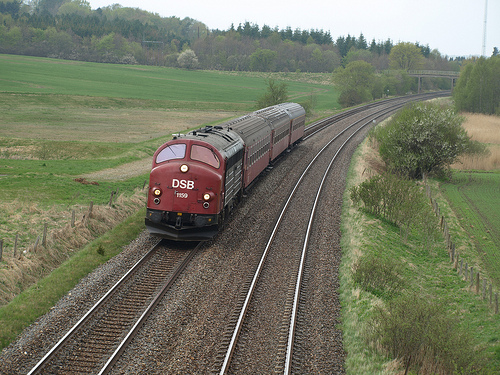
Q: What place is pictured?
A: It is a field.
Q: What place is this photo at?
A: It is at the field.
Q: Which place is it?
A: It is a field.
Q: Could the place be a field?
A: Yes, it is a field.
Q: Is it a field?
A: Yes, it is a field.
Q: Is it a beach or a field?
A: It is a field.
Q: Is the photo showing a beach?
A: No, the picture is showing a field.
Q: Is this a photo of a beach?
A: No, the picture is showing a field.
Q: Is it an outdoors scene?
A: Yes, it is outdoors.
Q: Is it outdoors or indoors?
A: It is outdoors.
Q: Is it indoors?
A: No, it is outdoors.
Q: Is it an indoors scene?
A: No, it is outdoors.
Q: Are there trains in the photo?
A: Yes, there is a train.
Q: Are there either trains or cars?
A: Yes, there is a train.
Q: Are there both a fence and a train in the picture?
A: Yes, there are both a train and a fence.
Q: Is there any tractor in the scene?
A: No, there are no tractors.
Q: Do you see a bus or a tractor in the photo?
A: No, there are no tractors or buses.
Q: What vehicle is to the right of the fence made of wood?
A: The vehicle is a train.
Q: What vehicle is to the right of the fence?
A: The vehicle is a train.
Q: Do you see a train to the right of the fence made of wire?
A: Yes, there is a train to the right of the fence.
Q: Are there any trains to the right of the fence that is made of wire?
A: Yes, there is a train to the right of the fence.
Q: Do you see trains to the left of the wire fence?
A: No, the train is to the right of the fence.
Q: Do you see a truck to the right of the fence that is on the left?
A: No, there is a train to the right of the fence.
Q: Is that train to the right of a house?
A: No, the train is to the right of a fence.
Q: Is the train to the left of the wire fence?
A: No, the train is to the right of the fence.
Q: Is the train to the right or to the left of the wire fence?
A: The train is to the right of the fence.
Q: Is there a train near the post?
A: Yes, there is a train near the post.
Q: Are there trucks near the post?
A: No, there is a train near the post.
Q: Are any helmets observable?
A: No, there are no helmets.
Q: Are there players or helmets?
A: No, there are no helmets or players.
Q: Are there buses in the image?
A: No, there are no buses.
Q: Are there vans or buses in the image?
A: No, there are no buses or vans.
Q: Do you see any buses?
A: No, there are no buses.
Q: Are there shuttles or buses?
A: No, there are no buses or shuttles.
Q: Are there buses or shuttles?
A: No, there are no buses or shuttles.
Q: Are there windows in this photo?
A: Yes, there is a window.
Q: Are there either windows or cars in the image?
A: Yes, there is a window.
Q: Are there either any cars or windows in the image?
A: Yes, there is a window.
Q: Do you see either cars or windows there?
A: Yes, there is a window.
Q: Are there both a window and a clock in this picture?
A: No, there is a window but no clocks.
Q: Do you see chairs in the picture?
A: No, there are no chairs.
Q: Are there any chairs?
A: No, there are no chairs.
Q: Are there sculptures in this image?
A: No, there are no sculptures.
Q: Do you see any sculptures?
A: No, there are no sculptures.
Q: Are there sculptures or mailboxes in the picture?
A: No, there are no sculptures or mailboxes.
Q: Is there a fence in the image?
A: Yes, there is a fence.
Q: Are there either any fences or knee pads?
A: Yes, there is a fence.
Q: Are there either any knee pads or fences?
A: Yes, there is a fence.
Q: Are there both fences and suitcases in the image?
A: No, there is a fence but no suitcases.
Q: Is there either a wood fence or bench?
A: Yes, there is a wood fence.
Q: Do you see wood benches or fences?
A: Yes, there is a wood fence.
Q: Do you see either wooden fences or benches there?
A: Yes, there is a wood fence.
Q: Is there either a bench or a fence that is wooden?
A: Yes, the fence is wooden.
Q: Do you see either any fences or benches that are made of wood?
A: Yes, the fence is made of wood.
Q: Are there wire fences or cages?
A: Yes, there is a wire fence.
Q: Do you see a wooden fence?
A: Yes, there is a wood fence.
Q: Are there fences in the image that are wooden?
A: Yes, there is a fence that is wooden.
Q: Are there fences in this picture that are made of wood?
A: Yes, there is a fence that is made of wood.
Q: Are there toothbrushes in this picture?
A: No, there are no toothbrushes.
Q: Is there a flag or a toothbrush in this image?
A: No, there are no toothbrushes or flags.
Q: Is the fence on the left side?
A: Yes, the fence is on the left of the image.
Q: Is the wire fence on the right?
A: No, the fence is on the left of the image.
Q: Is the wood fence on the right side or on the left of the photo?
A: The fence is on the left of the image.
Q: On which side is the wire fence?
A: The fence is on the left of the image.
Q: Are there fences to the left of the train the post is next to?
A: Yes, there is a fence to the left of the train.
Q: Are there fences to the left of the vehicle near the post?
A: Yes, there is a fence to the left of the train.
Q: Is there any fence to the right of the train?
A: No, the fence is to the left of the train.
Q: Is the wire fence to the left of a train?
A: Yes, the fence is to the left of a train.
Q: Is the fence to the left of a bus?
A: No, the fence is to the left of a train.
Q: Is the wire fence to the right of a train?
A: No, the fence is to the left of a train.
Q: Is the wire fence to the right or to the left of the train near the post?
A: The fence is to the left of the train.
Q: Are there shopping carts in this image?
A: No, there are no shopping carts.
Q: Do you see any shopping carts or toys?
A: No, there are no shopping carts or toys.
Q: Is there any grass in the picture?
A: Yes, there is grass.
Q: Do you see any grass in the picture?
A: Yes, there is grass.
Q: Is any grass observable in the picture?
A: Yes, there is grass.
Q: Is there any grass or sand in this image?
A: Yes, there is grass.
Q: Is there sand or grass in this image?
A: Yes, there is grass.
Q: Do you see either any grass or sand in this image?
A: Yes, there is grass.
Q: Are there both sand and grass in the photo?
A: No, there is grass but no sand.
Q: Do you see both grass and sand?
A: No, there is grass but no sand.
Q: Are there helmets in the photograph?
A: No, there are no helmets.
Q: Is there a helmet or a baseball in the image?
A: No, there are no helmets or baseballs.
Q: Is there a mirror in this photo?
A: No, there are no mirrors.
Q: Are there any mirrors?
A: No, there are no mirrors.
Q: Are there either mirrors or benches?
A: No, there are no mirrors or benches.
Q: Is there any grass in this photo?
A: Yes, there is grass.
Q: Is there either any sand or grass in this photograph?
A: Yes, there is grass.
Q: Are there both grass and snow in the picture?
A: No, there is grass but no snow.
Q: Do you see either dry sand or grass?
A: Yes, there is dry grass.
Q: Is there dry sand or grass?
A: Yes, there is dry grass.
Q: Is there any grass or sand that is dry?
A: Yes, the grass is dry.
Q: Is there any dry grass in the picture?
A: Yes, there is dry grass.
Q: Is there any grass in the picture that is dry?
A: Yes, there is grass that is dry.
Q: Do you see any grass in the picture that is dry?
A: Yes, there is grass that is dry.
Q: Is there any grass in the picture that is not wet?
A: Yes, there is dry grass.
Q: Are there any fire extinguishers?
A: No, there are no fire extinguishers.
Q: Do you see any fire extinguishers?
A: No, there are no fire extinguishers.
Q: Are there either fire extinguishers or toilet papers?
A: No, there are no fire extinguishers or toilet papers.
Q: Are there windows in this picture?
A: Yes, there is a window.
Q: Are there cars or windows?
A: Yes, there is a window.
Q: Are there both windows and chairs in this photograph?
A: No, there is a window but no chairs.